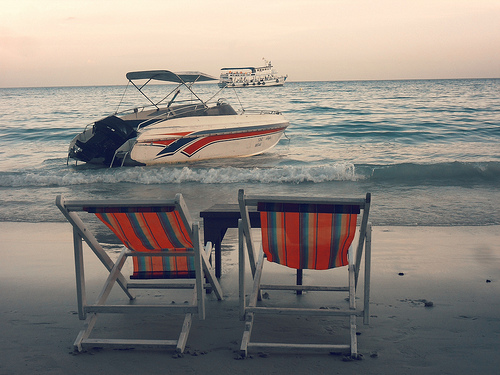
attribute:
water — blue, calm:
[1, 78, 498, 222]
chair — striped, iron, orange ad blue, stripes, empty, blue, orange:
[56, 192, 225, 357]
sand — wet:
[1, 222, 498, 373]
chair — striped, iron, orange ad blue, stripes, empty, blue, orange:
[232, 188, 375, 358]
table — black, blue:
[200, 201, 262, 295]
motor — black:
[66, 115, 137, 165]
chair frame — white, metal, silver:
[54, 193, 223, 356]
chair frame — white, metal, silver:
[235, 188, 372, 362]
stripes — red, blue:
[135, 126, 285, 160]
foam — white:
[1, 159, 355, 187]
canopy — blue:
[125, 68, 219, 83]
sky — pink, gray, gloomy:
[1, 5, 497, 91]